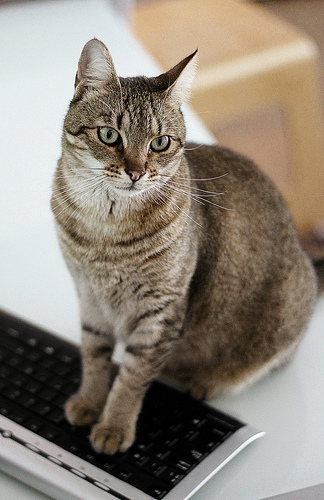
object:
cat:
[49, 36, 320, 455]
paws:
[62, 393, 105, 426]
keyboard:
[0, 307, 266, 500]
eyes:
[95, 123, 125, 151]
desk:
[0, 0, 322, 499]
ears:
[74, 38, 122, 91]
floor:
[224, 10, 323, 146]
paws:
[90, 420, 135, 456]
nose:
[127, 168, 146, 182]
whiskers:
[45, 167, 232, 228]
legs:
[101, 318, 179, 422]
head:
[62, 35, 198, 200]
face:
[94, 113, 180, 198]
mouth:
[116, 184, 143, 196]